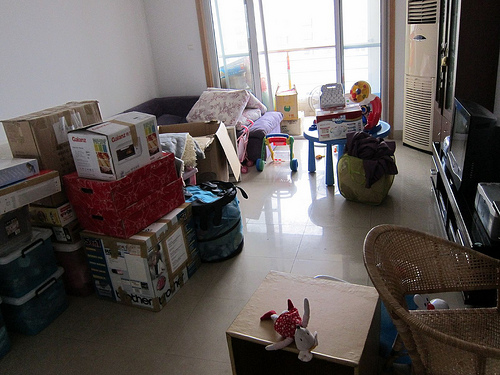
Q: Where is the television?
A: To the right.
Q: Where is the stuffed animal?
A: On the box.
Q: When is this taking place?
A: During the daytime.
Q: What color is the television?
A: Black.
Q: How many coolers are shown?
A: 2 coolers.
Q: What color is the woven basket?
A: Brown.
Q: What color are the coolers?
A: Blue.